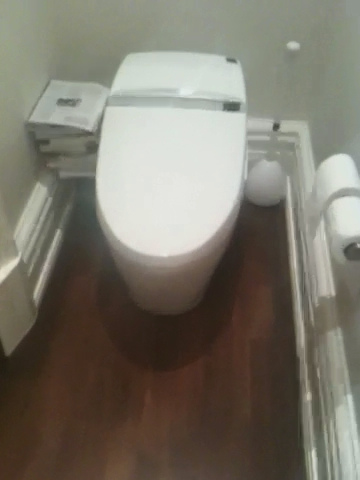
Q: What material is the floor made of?
A: Wood.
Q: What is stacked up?
A: Books.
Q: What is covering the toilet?
A: The toilet lid.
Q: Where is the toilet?
A: In the bathroom.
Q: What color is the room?
A: White.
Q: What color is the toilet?
A: White.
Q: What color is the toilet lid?
A: White.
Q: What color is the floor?
A: Brown.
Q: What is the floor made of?
A: Wood.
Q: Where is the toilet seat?
A: Top of toilet.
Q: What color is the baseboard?
A: White.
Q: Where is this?
A: Bathroom.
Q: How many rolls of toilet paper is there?
A: 2.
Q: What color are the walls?
A: Grey.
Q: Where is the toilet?
A: Bathroom.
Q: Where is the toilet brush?
A: Beside the toilet.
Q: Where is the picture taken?
A: Bathroom.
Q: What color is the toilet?
A: White.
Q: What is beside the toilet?
A: Books.